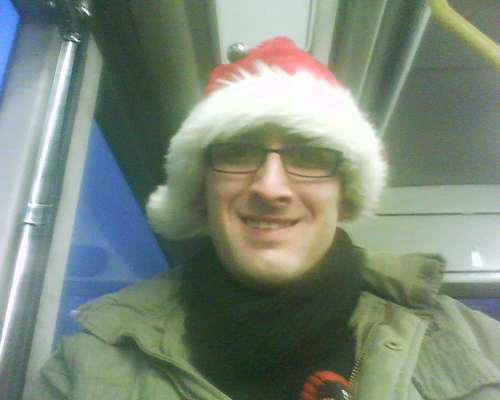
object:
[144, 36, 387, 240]
santa hat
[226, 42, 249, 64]
bell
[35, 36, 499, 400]
man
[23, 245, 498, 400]
coat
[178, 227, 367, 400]
scarf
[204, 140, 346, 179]
glasses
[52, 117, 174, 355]
window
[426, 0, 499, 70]
handle bar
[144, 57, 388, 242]
brim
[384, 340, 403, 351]
button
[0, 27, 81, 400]
pipe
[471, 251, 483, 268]
reflection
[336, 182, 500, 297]
wall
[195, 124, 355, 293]
face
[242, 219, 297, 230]
teeth